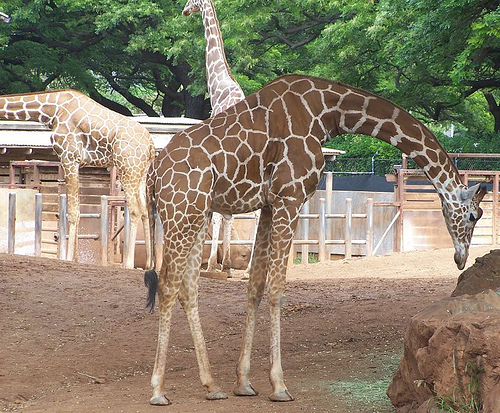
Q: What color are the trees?
A: Green.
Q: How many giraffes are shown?
A: Three.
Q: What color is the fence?
A: Tan.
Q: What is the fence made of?
A: Wood.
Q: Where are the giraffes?
A: Behind fence.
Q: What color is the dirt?
A: Brown.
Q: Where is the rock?
A: In dirt.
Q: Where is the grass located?
A: In dirt.